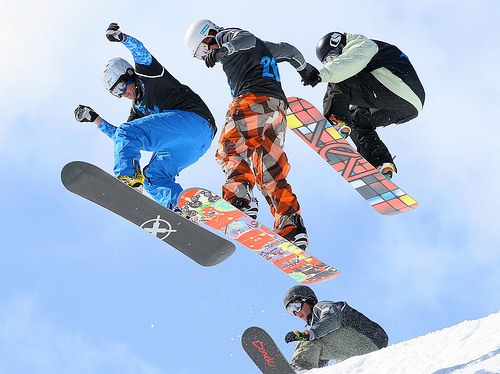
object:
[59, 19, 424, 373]
skiers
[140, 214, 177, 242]
image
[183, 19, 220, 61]
helmet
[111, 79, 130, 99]
googles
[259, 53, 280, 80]
number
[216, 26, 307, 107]
shirt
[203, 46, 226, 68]
glove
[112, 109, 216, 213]
pants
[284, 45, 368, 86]
hands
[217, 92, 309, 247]
ski pants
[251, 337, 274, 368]
writing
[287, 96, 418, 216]
snowboard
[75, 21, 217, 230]
man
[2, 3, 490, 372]
sky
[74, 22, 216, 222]
snowboarder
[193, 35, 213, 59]
googles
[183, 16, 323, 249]
skier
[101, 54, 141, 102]
head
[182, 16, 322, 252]
man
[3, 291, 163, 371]
clouds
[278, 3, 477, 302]
clouds